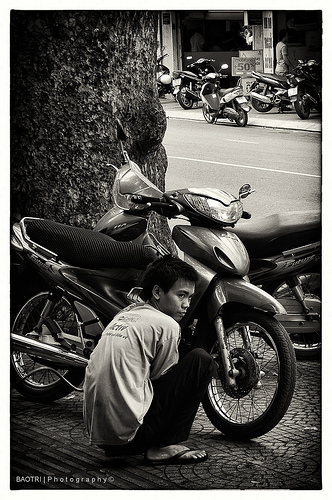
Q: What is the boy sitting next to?
A: A motorbike.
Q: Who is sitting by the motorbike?
A: A boy.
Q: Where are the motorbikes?
A: Next to a street.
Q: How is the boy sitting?
A: In a crouching position.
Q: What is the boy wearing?
A: Flip Flops.